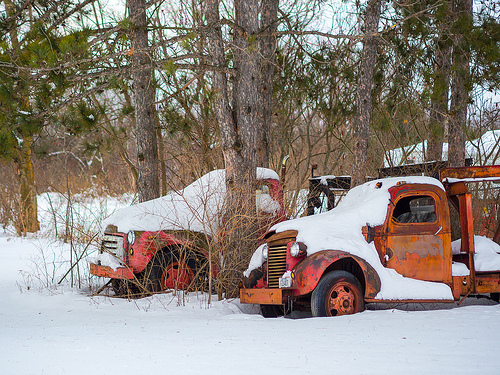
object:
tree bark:
[229, 54, 261, 266]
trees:
[280, 1, 499, 181]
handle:
[434, 226, 443, 235]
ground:
[0, 200, 492, 374]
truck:
[86, 156, 473, 300]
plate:
[278, 277, 292, 288]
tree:
[0, 0, 166, 237]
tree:
[194, 0, 272, 300]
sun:
[73, 314, 408, 373]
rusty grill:
[267, 243, 288, 287]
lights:
[373, 180, 384, 192]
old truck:
[238, 165, 500, 318]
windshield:
[340, 189, 387, 223]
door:
[383, 183, 453, 289]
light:
[289, 241, 307, 258]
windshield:
[187, 179, 229, 206]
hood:
[269, 175, 453, 301]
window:
[392, 194, 438, 223]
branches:
[168, 160, 320, 307]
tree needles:
[2, 32, 103, 159]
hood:
[87, 166, 281, 270]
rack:
[441, 180, 500, 272]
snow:
[0, 131, 499, 374]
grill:
[96, 231, 126, 266]